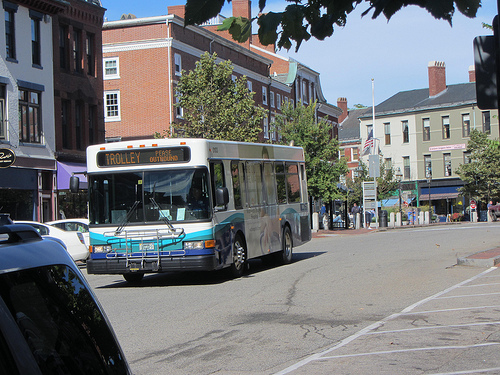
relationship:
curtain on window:
[463, 114, 469, 122] [462, 114, 471, 136]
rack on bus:
[104, 229, 188, 269] [87, 138, 313, 282]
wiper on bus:
[149, 197, 175, 233] [87, 138, 313, 282]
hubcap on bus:
[233, 242, 245, 271] [87, 138, 313, 282]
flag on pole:
[364, 130, 373, 149] [370, 78, 379, 229]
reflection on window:
[53, 266, 120, 363] [1, 265, 128, 375]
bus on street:
[87, 138, 313, 282] [1, 223, 500, 375]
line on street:
[273, 262, 500, 375] [1, 223, 500, 375]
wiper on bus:
[116, 201, 140, 235] [87, 138, 313, 282]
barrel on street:
[379, 211, 388, 229] [1, 223, 500, 375]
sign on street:
[470, 200, 478, 210] [1, 223, 500, 375]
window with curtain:
[462, 114, 471, 136] [463, 114, 469, 122]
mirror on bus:
[215, 188, 228, 213] [87, 138, 313, 282]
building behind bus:
[103, 14, 271, 143] [87, 138, 313, 282]